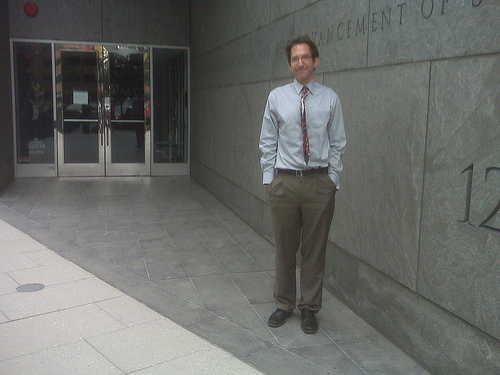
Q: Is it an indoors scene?
A: Yes, it is indoors.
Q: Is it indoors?
A: Yes, it is indoors.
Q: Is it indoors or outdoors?
A: It is indoors.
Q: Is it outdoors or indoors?
A: It is indoors.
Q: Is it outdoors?
A: No, it is indoors.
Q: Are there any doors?
A: Yes, there are doors.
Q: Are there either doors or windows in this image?
A: Yes, there are doors.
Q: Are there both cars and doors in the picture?
A: No, there are doors but no cars.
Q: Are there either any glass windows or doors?
A: Yes, there are glass doors.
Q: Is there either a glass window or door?
A: Yes, there are glass doors.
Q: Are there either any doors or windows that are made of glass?
A: Yes, the doors are made of glass.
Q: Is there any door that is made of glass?
A: Yes, there are doors that are made of glass.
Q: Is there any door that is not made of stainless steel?
A: Yes, there are doors that are made of glass.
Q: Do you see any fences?
A: No, there are no fences.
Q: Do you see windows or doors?
A: Yes, there is a door.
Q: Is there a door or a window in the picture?
A: Yes, there is a door.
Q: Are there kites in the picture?
A: No, there are no kites.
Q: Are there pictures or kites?
A: No, there are no kites or pictures.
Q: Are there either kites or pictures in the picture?
A: No, there are no kites or pictures.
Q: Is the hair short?
A: Yes, the hair is short.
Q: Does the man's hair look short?
A: Yes, the hair is short.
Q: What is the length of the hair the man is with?
A: The hair is short.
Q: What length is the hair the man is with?
A: The hair is short.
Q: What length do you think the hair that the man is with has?
A: The hair has short length.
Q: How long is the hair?
A: The hair is short.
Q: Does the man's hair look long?
A: No, the hair is short.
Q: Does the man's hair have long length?
A: No, the hair is short.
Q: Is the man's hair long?
A: No, the hair is short.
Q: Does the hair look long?
A: No, the hair is short.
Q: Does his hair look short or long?
A: The hair is short.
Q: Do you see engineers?
A: No, there are no engineers.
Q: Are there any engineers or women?
A: No, there are no engineers or women.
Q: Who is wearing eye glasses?
A: The man is wearing eye glasses.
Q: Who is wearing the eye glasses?
A: The man is wearing eye glasses.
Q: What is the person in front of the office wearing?
A: The man is wearing eye glasses.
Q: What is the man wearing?
A: The man is wearing eye glasses.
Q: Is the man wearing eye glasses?
A: Yes, the man is wearing eye glasses.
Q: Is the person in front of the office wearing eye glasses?
A: Yes, the man is wearing eye glasses.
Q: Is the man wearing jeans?
A: No, the man is wearing eye glasses.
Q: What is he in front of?
A: The man is in front of the office.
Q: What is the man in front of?
A: The man is in front of the office.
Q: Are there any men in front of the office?
A: Yes, there is a man in front of the office.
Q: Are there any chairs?
A: No, there are no chairs.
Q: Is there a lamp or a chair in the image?
A: No, there are no chairs or lamps.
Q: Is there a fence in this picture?
A: No, there are no fences.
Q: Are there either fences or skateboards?
A: No, there are no fences or skateboards.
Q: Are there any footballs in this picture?
A: No, there are no footballs.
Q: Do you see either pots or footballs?
A: No, there are no footballs or pots.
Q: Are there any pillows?
A: No, there are no pillows.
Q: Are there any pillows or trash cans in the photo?
A: No, there are no pillows or trash cans.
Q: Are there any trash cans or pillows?
A: No, there are no pillows or trash cans.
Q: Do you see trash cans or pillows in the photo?
A: No, there are no pillows or trash cans.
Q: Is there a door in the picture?
A: Yes, there is a door.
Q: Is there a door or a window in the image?
A: Yes, there is a door.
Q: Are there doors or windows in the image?
A: Yes, there is a door.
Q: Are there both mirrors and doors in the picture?
A: No, there is a door but no mirrors.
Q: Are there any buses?
A: No, there are no buses.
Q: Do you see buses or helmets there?
A: No, there are no buses or helmets.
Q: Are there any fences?
A: No, there are no fences.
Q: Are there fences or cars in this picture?
A: No, there are no fences or cars.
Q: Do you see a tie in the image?
A: Yes, there is a tie.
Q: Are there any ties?
A: Yes, there is a tie.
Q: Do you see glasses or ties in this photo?
A: Yes, there is a tie.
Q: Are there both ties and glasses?
A: Yes, there are both a tie and glasses.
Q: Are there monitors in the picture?
A: No, there are no monitors.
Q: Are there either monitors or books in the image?
A: No, there are no monitors or books.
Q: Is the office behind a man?
A: Yes, the office is behind a man.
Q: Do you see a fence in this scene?
A: No, there are no fences.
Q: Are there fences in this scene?
A: No, there are no fences.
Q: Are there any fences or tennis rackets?
A: No, there are no fences or tennis rackets.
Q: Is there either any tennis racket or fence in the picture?
A: No, there are no fences or rackets.